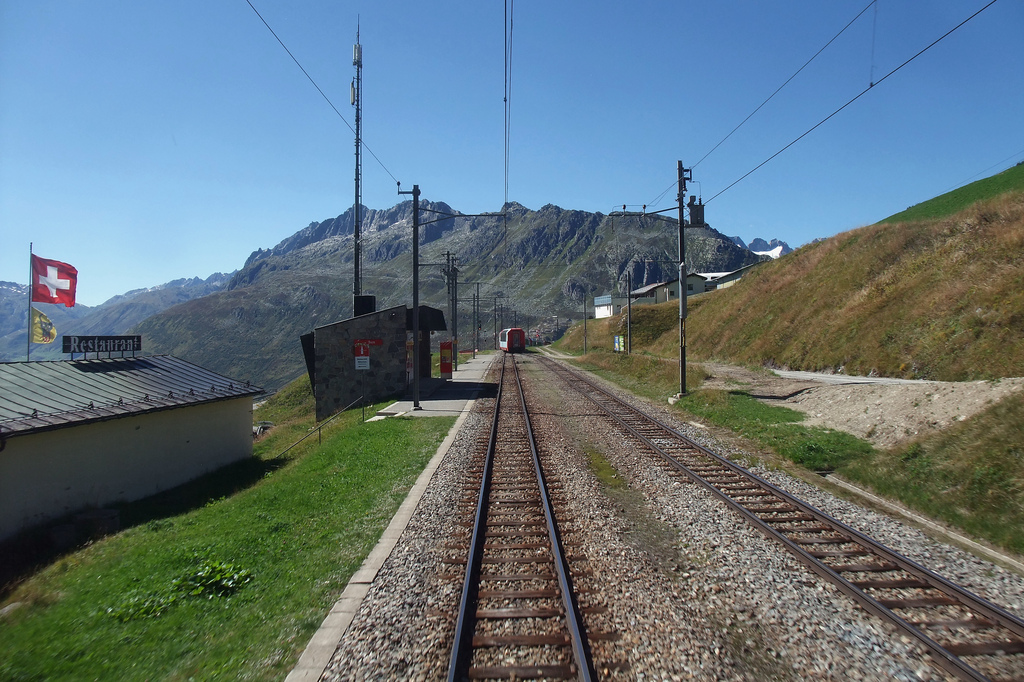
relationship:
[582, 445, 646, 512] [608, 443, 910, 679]
grass growing among gravel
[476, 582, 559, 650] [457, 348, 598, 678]
planks below rail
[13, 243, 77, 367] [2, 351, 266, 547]
flag on building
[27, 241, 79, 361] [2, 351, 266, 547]
flag on building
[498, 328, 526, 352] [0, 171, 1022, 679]
train on ground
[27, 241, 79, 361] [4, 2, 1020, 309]
flag flying in air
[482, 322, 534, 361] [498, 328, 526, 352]
train on train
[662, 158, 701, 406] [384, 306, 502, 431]
pole in ground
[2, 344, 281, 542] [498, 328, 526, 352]
building on side of train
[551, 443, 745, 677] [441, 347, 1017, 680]
gravel around rails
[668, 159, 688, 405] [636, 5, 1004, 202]
pole holding wires